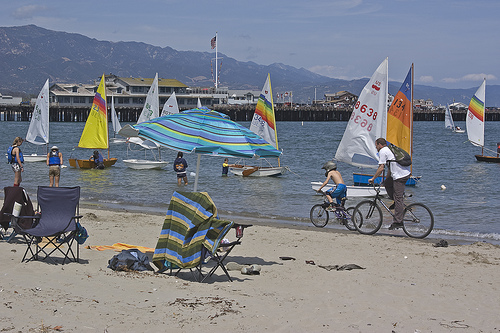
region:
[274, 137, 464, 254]
Riding bikes along the beach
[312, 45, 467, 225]
Sail boats in the water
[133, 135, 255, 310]
Chair on the beach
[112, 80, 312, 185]
Umbrella on the beach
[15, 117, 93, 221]
People with life vest on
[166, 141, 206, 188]
Girl in the water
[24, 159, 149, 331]
Chair sitting in the sand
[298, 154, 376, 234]
Boy with a helmet on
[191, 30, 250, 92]
Flag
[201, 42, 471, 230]
Sailboats sailing in the water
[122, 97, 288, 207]
Parasol is blue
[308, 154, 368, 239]
Kid riding a bike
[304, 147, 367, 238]
Kid wears a blue short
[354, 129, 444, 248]
Person wears a white t-shirt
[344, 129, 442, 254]
Person carries a backpack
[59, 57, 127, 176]
Boat with a yellow sailing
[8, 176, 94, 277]
Foldable chair is blue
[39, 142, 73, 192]
Person wears blue vest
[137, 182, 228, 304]
Towel is green, blue and yellow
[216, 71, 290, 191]
Person stand next to a white boat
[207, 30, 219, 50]
a flag blowing in the wind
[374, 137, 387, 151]
the head of a man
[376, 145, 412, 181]
a white tee shirt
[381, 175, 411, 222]
a pair of gray pants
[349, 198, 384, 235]
a black bike tire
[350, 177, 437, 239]
a bicycle on the beach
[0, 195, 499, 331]
a sandy brown beach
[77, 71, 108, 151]
a yellow sail on a boat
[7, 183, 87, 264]
a navy blue chair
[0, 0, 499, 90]
a cloudy blue sky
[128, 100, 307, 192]
blue, purple and yellow striped beach umbrella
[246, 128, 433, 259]
riding bicycles along beach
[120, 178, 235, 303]
Avacado green, blue and gold beach towel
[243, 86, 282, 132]
A lovely rainbow accent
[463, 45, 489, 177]
a wind blown sail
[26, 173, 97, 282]
an unoccupied folding lawn chair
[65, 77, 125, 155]
A bight yellow sail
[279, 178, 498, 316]
a sandy beach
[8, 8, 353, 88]
mountain tops in the distance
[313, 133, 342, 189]
a young boy wearing a helmet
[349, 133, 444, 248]
person riding a bicycle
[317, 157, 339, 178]
helmet on a persons head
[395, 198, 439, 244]
rear wheel on a bicycle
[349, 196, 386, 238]
front wheel on a bicycle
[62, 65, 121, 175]
sailboat in the water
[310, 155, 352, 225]
person with blue shorts riding a bicycle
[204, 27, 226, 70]
flag on a pole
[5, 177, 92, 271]
chair in the sand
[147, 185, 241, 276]
towel on a chair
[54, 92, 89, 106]
windows on a building